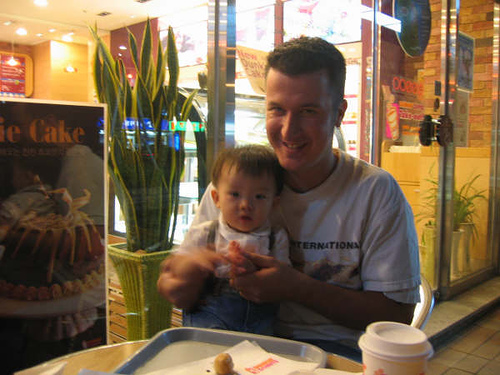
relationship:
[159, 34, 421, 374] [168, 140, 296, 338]
man has a baby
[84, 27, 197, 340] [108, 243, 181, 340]
plant in a pot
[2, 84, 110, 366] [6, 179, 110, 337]
sign has a cake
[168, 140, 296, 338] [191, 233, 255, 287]
boy has hands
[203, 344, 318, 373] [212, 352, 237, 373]
napkin with a donut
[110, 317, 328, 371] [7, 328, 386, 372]
tray on table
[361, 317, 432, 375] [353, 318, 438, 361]
cup has a lid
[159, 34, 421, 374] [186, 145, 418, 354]
man has a shirt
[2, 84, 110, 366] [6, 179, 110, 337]
ad has a cake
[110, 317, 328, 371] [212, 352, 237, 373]
tray has a morsel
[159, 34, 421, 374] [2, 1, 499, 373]
man in a restaraunt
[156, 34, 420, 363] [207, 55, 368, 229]
man looking at camera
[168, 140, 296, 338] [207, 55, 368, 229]
one person looking at camera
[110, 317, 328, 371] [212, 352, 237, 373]
tray has appetizers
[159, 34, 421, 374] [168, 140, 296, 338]
man holds son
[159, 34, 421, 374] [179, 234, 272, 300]
father holding hand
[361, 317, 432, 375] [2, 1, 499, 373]
cup from restaraunt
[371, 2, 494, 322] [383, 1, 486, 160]
door has a sign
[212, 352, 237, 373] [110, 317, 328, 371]
food on tray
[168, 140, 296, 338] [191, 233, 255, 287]
baby has hands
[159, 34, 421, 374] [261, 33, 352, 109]
man has hair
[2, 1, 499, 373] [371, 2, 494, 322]
shop has a door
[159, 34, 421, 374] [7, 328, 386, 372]
man at table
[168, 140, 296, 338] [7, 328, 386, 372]
baby at table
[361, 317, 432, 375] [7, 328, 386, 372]
cup on table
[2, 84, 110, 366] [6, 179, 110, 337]
ad has cake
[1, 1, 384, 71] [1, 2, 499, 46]
ceiling has lights